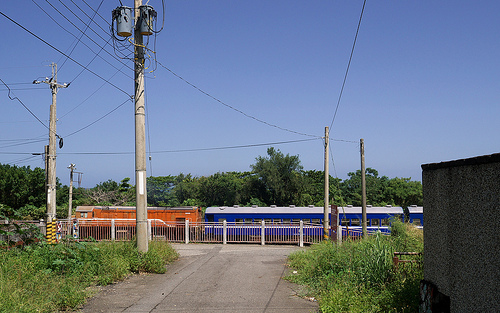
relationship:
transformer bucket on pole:
[113, 4, 131, 36] [132, 2, 149, 252]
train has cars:
[59, 192, 436, 259] [201, 194, 346, 244]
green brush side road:
[263, 217, 455, 311] [162, 237, 314, 302]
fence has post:
[47, 213, 412, 250] [297, 217, 309, 247]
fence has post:
[47, 213, 412, 250] [259, 212, 267, 241]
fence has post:
[47, 213, 412, 250] [219, 215, 229, 242]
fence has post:
[47, 213, 412, 250] [179, 210, 191, 244]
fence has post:
[47, 213, 412, 250] [105, 211, 115, 241]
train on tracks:
[68, 201, 435, 246] [45, 234, 415, 249]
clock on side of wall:
[367, 219, 397, 254] [212, 205, 428, 249]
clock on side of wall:
[404, 276, 453, 304] [5, 207, 77, 245]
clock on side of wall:
[235, 178, 253, 207] [405, 154, 475, 302]